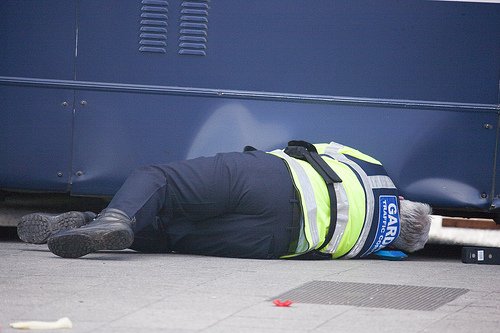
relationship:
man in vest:
[15, 138, 435, 266] [280, 132, 397, 261]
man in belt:
[15, 138, 435, 266] [292, 190, 303, 260]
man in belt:
[15, 138, 435, 266] [291, 133, 343, 262]